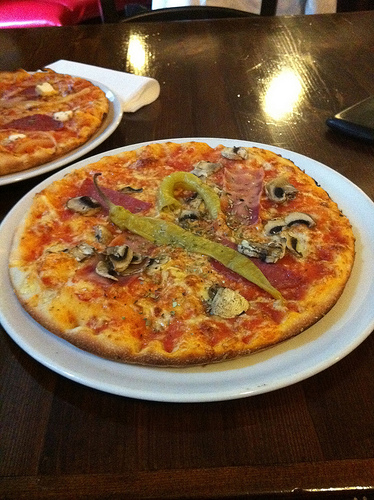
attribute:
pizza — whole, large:
[4, 129, 360, 375]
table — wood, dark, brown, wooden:
[177, 21, 320, 111]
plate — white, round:
[335, 182, 352, 197]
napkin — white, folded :
[107, 65, 147, 92]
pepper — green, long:
[162, 174, 209, 212]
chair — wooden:
[95, 1, 280, 15]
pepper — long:
[114, 209, 184, 237]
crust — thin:
[15, 233, 20, 260]